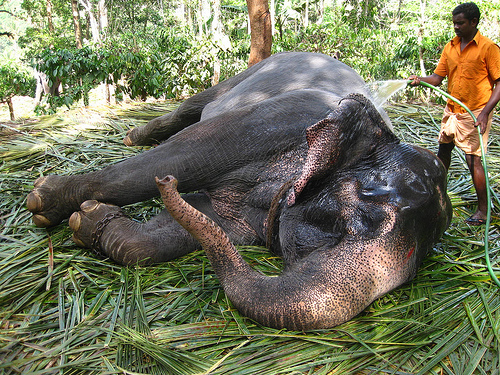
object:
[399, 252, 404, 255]
dot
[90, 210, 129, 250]
chain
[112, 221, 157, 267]
ankle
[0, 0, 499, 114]
trees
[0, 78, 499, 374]
doorway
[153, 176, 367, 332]
trunk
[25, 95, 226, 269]
leg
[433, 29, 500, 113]
shirt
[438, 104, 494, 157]
shorts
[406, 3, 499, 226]
man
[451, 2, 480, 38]
head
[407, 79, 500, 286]
hose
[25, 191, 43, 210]
nails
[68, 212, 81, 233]
nails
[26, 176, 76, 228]
foot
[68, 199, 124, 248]
foot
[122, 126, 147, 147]
foot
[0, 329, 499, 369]
fronds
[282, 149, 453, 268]
face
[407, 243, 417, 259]
blood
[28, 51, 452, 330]
elephant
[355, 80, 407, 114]
water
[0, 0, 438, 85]
leaves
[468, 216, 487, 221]
flip flot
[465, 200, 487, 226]
foot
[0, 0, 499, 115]
background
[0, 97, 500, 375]
ground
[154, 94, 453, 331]
elephant's forehead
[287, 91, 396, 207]
ear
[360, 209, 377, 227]
eye